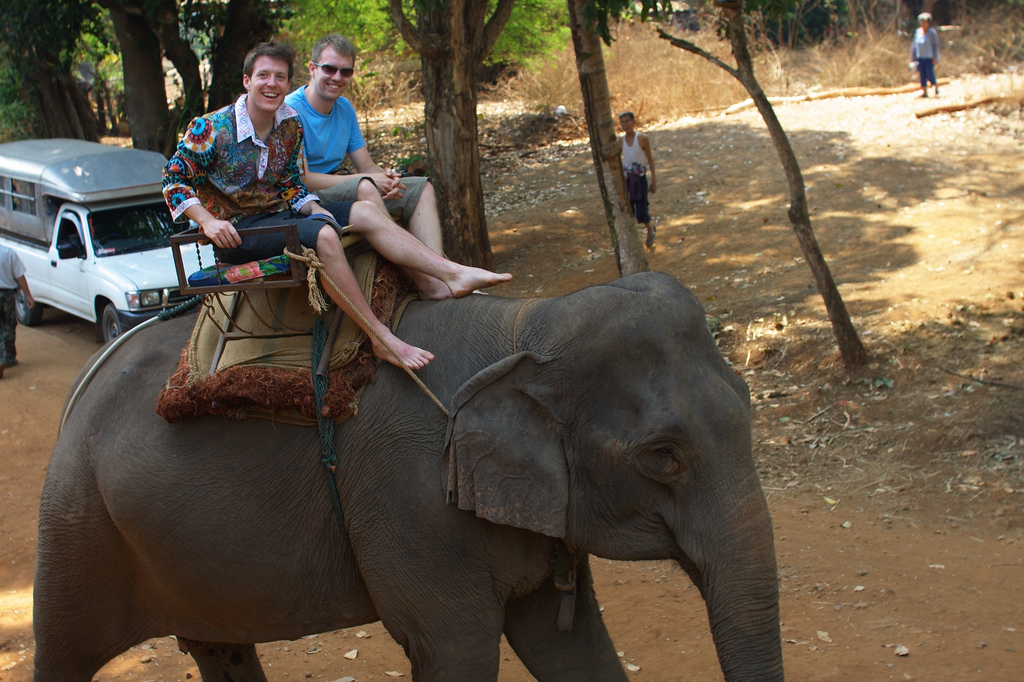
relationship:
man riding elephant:
[162, 44, 512, 373] [32, 276, 786, 670]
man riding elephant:
[281, 29, 454, 297] [32, 276, 786, 670]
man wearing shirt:
[162, 44, 512, 373] [154, 97, 323, 234]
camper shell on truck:
[1, 135, 170, 244] [0, 203, 216, 346]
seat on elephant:
[152, 203, 421, 422] [30, 245, 802, 675]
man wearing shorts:
[162, 44, 512, 373] [198, 211, 338, 257]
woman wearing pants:
[906, 8, 946, 97] [909, 62, 947, 94]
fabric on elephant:
[138, 261, 402, 383] [32, 276, 786, 670]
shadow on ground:
[401, 107, 1020, 432] [0, 59, 1018, 679]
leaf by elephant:
[335, 645, 367, 662] [32, 276, 786, 670]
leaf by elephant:
[343, 634, 393, 660] [32, 276, 786, 670]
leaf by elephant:
[375, 666, 402, 679] [32, 276, 786, 670]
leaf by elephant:
[615, 652, 654, 676] [32, 276, 786, 670]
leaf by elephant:
[875, 626, 925, 657] [32, 276, 786, 670]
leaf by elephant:
[816, 624, 829, 641] [30, 245, 802, 675]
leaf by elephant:
[807, 479, 839, 503] [30, 245, 802, 675]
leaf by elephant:
[833, 508, 847, 528] [30, 245, 802, 675]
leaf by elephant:
[921, 551, 941, 565] [32, 276, 786, 670]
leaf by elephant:
[763, 383, 784, 402] [30, 245, 802, 675]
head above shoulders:
[236, 46, 300, 107] [192, 100, 313, 142]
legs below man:
[309, 170, 511, 374] [315, 184, 518, 361]